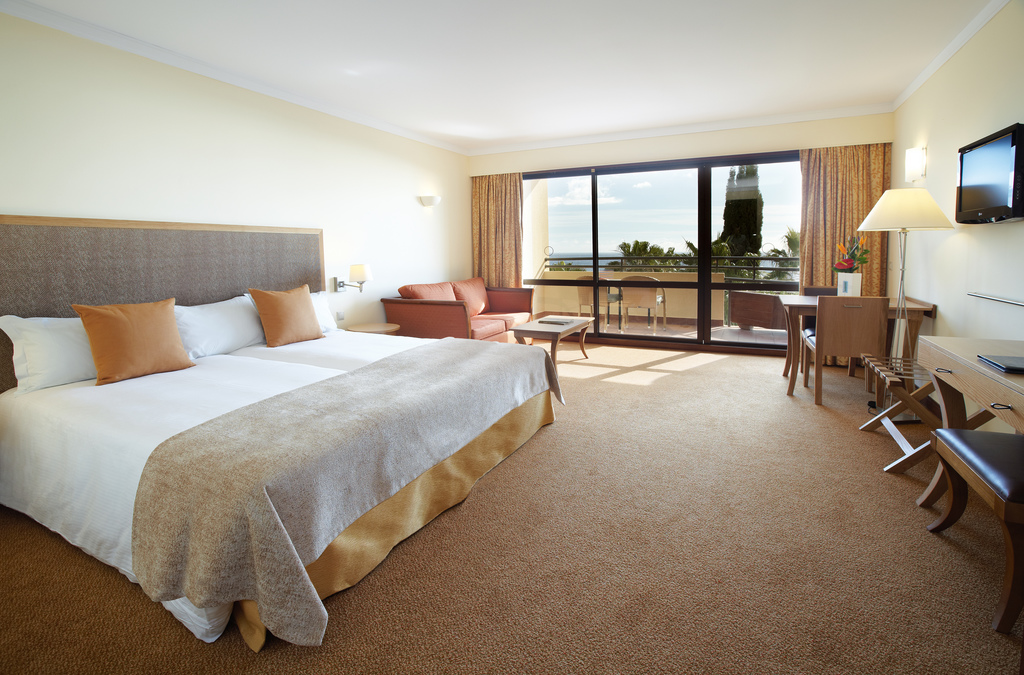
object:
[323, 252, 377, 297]
light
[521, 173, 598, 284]
glass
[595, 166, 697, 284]
glass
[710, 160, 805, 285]
glass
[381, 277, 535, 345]
sofa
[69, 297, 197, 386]
pillow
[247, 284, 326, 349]
pillow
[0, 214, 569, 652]
bed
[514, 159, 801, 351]
windows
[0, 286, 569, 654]
sheets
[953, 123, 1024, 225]
tv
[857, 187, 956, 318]
lamp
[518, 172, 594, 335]
window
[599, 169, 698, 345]
window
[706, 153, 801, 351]
window